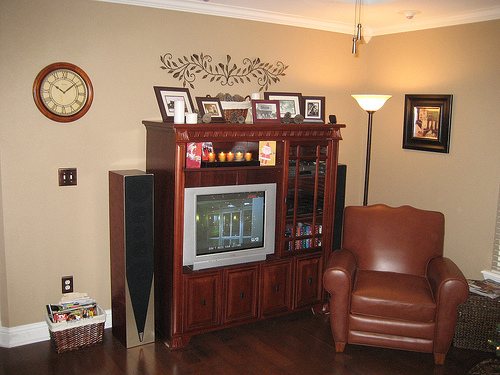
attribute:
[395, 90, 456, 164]
frame — black, wood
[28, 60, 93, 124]
frame — brown, wood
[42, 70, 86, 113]
face — beige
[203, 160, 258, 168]
tray — black